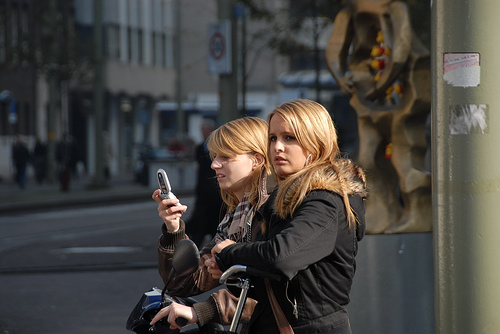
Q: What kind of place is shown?
A: It is a street.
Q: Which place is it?
A: It is a street.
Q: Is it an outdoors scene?
A: Yes, it is outdoors.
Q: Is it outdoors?
A: Yes, it is outdoors.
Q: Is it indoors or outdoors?
A: It is outdoors.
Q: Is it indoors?
A: No, it is outdoors.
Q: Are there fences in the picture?
A: No, there are no fences.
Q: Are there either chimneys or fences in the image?
A: No, there are no fences or chimneys.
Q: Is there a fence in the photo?
A: No, there are no fences.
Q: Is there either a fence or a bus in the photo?
A: No, there are no fences or buses.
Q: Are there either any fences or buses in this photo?
A: No, there are no fences or buses.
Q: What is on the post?
A: The sign is on the post.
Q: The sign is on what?
A: The sign is on the post.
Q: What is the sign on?
A: The sign is on the post.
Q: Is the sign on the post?
A: Yes, the sign is on the post.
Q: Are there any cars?
A: No, there are no cars.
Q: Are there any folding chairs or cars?
A: No, there are no cars or folding chairs.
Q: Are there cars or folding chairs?
A: No, there are no cars or folding chairs.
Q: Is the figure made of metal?
A: Yes, the figure is made of metal.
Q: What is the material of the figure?
A: The figure is made of metal.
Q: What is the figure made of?
A: The figure is made of metal.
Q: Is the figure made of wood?
A: No, the figure is made of metal.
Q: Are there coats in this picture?
A: Yes, there is a coat.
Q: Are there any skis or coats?
A: Yes, there is a coat.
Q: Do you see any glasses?
A: No, there are no glasses.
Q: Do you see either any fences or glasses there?
A: No, there are no glasses or fences.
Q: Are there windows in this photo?
A: Yes, there is a window.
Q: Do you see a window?
A: Yes, there is a window.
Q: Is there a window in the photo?
A: Yes, there is a window.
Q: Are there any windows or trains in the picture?
A: Yes, there is a window.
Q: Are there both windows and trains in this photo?
A: No, there is a window but no trains.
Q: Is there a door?
A: No, there are no doors.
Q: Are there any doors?
A: No, there are no doors.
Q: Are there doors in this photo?
A: No, there are no doors.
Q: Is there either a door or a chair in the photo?
A: No, there are no doors or chairs.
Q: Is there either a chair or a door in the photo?
A: No, there are no doors or chairs.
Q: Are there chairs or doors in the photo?
A: No, there are no doors or chairs.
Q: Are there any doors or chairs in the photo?
A: No, there are no doors or chairs.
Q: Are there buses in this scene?
A: No, there are no buses.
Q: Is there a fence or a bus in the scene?
A: No, there are no buses or fences.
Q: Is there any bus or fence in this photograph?
A: No, there are no buses or fences.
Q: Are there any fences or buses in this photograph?
A: No, there are no buses or fences.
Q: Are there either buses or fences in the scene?
A: No, there are no buses or fences.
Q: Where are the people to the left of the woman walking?
A: The people are walking on the sidewalk.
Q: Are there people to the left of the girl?
A: Yes, there are people to the left of the girl.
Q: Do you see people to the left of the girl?
A: Yes, there are people to the left of the girl.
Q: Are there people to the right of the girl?
A: No, the people are to the left of the girl.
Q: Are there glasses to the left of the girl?
A: No, there are people to the left of the girl.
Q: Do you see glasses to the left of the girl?
A: No, there are people to the left of the girl.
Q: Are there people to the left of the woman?
A: Yes, there are people to the left of the woman.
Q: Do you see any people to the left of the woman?
A: Yes, there are people to the left of the woman.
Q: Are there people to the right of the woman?
A: No, the people are to the left of the woman.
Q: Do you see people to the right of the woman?
A: No, the people are to the left of the woman.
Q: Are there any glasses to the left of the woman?
A: No, there are people to the left of the woman.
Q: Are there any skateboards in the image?
A: No, there are no skateboards.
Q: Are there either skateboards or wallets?
A: No, there are no skateboards or wallets.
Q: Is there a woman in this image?
A: Yes, there is a woman.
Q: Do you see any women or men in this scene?
A: Yes, there is a woman.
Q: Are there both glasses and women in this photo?
A: No, there is a woman but no glasses.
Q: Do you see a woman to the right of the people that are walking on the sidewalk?
A: Yes, there is a woman to the right of the people.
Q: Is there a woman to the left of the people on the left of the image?
A: No, the woman is to the right of the people.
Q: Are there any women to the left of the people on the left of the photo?
A: No, the woman is to the right of the people.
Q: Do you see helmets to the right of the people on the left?
A: No, there is a woman to the right of the people.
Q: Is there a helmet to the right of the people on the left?
A: No, there is a woman to the right of the people.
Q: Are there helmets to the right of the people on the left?
A: No, there is a woman to the right of the people.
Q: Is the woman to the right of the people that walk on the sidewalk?
A: Yes, the woman is to the right of the people.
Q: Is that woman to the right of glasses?
A: No, the woman is to the right of the people.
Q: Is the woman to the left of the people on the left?
A: No, the woman is to the right of the people.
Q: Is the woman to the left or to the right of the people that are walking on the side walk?
A: The woman is to the right of the people.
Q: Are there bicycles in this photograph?
A: No, there are no bicycles.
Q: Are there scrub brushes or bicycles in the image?
A: No, there are no bicycles or scrub brushes.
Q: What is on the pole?
A: The sticker is on the pole.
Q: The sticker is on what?
A: The sticker is on the pole.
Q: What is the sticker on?
A: The sticker is on the pole.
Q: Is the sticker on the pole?
A: Yes, the sticker is on the pole.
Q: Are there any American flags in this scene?
A: No, there are no American flags.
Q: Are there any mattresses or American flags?
A: No, there are no American flags or mattresses.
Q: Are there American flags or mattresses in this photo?
A: No, there are no American flags or mattresses.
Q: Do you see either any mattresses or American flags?
A: No, there are no American flags or mattresses.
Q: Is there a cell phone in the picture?
A: Yes, there is a cell phone.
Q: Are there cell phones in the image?
A: Yes, there is a cell phone.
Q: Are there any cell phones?
A: Yes, there is a cell phone.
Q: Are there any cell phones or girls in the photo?
A: Yes, there is a cell phone.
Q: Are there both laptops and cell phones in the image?
A: No, there is a cell phone but no laptops.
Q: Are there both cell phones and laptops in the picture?
A: No, there is a cell phone but no laptops.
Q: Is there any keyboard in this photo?
A: No, there are no keyboards.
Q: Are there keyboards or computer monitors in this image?
A: No, there are no keyboards or computer monitors.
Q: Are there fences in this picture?
A: No, there are no fences.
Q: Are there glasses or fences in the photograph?
A: No, there are no fences or glasses.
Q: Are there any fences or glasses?
A: No, there are no fences or glasses.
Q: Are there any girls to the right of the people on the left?
A: Yes, there is a girl to the right of the people.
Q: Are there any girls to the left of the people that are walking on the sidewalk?
A: No, the girl is to the right of the people.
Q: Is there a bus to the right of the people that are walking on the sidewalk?
A: No, there is a girl to the right of the people.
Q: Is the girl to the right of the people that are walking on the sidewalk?
A: Yes, the girl is to the right of the people.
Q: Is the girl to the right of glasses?
A: No, the girl is to the right of the people.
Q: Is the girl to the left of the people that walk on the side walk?
A: No, the girl is to the right of the people.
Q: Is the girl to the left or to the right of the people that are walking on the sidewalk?
A: The girl is to the right of the people.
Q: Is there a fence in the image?
A: No, there are no fences.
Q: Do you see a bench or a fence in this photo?
A: No, there are no fences or benches.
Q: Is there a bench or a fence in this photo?
A: No, there are no fences or benches.